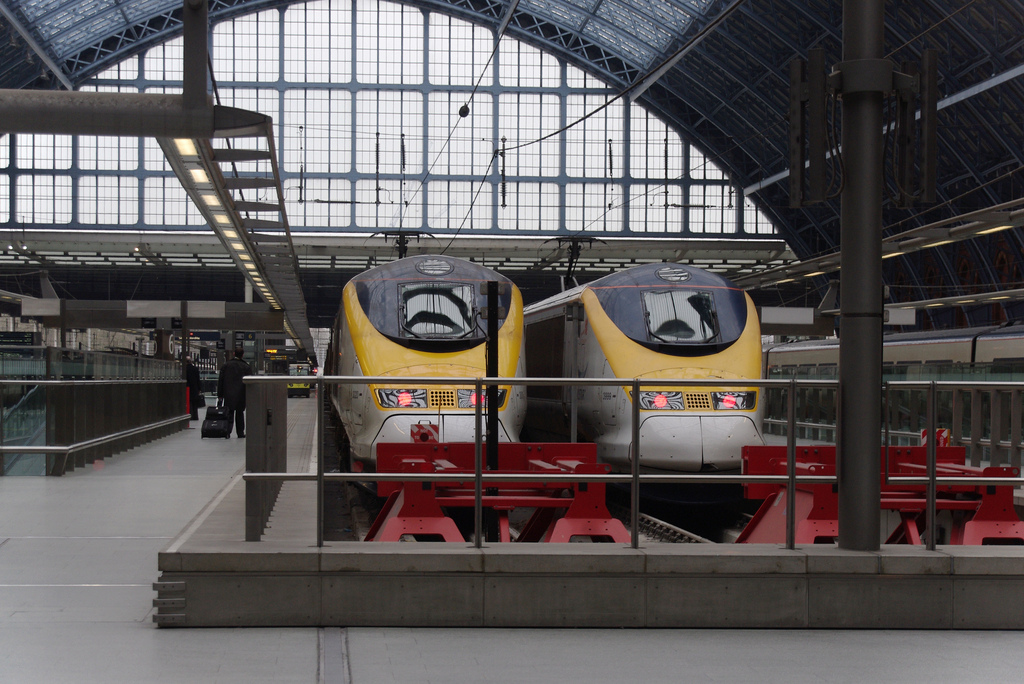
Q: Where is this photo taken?
A: The train station.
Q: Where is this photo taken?
A: Speedline station.